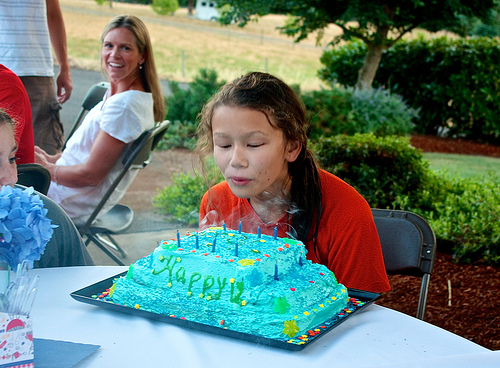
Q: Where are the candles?
A: Cake.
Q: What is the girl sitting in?
A: Chair.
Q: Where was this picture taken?
A: Park.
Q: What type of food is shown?
A: Cake.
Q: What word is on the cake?
A: Happy.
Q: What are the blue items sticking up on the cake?
A: Candles.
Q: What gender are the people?
A: Female.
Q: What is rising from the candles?
A: Smoke.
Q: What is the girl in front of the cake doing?
A: Blowing out the candles.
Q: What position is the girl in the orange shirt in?
A: Sitting.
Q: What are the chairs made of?
A: Plastic and metal.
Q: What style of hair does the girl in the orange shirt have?
A: Long hair.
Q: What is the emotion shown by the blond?
A: Joy.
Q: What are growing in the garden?
A: Plants.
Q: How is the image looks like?
A: Good.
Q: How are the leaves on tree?
A: Fresh.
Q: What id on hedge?
A: Green leaves.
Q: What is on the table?
A: Cake.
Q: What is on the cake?
A: Candle.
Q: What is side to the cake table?
A: Folding chair.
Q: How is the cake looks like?
A: 3 layer.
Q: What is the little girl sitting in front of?
A: Blue cake.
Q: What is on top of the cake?
A: Candles.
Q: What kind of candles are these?
A: Blue candles.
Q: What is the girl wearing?
A: Red short sleeve shirt.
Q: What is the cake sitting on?
A: Blue tray.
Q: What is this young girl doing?
A: Blowing candles.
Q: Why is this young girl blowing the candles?
A: It's her birthday.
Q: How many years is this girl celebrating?
A: Twelve.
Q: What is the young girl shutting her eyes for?
A: To make a wish.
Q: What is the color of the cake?
A: Blue.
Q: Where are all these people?
A: At a birthday party.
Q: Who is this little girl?
A: A birthday girl.